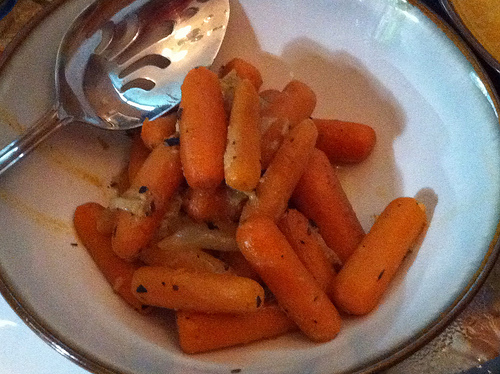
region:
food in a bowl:
[145, 80, 346, 255]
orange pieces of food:
[229, 209, 339, 336]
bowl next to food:
[432, 226, 478, 276]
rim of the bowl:
[406, 285, 475, 347]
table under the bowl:
[458, 311, 491, 349]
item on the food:
[131, 272, 155, 305]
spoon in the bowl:
[6, 24, 193, 210]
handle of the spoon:
[16, 88, 66, 173]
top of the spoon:
[65, 6, 217, 126]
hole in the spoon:
[124, 49, 176, 80]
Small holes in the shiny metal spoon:
[91, 13, 175, 98]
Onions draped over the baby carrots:
[104, 182, 159, 224]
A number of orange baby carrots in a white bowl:
[103, 76, 408, 326]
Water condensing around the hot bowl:
[442, 321, 483, 356]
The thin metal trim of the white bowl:
[365, 342, 437, 370]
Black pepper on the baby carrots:
[275, 233, 310, 267]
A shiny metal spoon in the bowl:
[0, 5, 240, 220]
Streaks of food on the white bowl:
[10, 142, 107, 225]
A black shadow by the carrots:
[304, 52, 424, 199]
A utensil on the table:
[426, 1, 496, 81]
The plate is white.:
[2, 1, 498, 372]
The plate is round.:
[1, 2, 498, 372]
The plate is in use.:
[4, 0, 497, 371]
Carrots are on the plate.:
[2, 0, 499, 371]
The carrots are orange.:
[1, 0, 498, 371]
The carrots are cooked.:
[2, 2, 499, 371]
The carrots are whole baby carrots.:
[2, 3, 498, 371]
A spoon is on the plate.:
[2, 0, 499, 372]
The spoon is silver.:
[3, 1, 498, 372]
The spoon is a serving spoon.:
[1, 0, 498, 370]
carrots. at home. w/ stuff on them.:
[0, 2, 498, 372]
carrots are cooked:
[70, 50, 434, 361]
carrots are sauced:
[0, 54, 436, 348]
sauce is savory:
[70, 129, 400, 323]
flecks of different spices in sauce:
[51, 125, 393, 322]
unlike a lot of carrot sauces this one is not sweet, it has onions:
[92, 156, 252, 261]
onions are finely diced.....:
[80, 145, 161, 231]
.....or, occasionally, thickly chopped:
[150, 170, 254, 261]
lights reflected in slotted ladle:
[96, 7, 229, 114]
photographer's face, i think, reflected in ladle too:
[169, 0, 215, 28]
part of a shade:
[352, 57, 414, 97]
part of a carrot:
[204, 318, 236, 350]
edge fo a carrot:
[345, 285, 363, 297]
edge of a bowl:
[399, 322, 426, 349]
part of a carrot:
[303, 327, 311, 339]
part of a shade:
[398, 247, 436, 293]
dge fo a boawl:
[406, 310, 434, 343]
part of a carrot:
[223, 298, 273, 359]